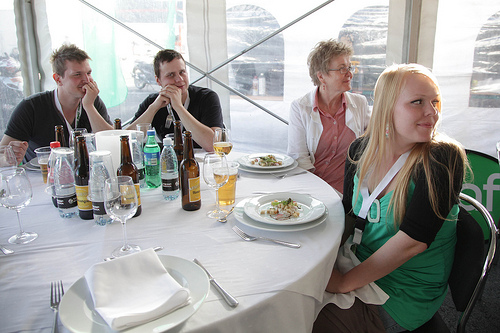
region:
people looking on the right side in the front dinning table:
[202, 10, 490, 307]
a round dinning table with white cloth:
[7, 137, 340, 331]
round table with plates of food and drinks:
[4, 122, 330, 308]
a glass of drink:
[209, 122, 236, 157]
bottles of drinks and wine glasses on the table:
[31, 117, 243, 239]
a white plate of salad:
[231, 177, 328, 249]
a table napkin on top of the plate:
[35, 235, 222, 331]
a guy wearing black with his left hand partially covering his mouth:
[2, 37, 128, 201]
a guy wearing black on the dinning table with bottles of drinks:
[123, 33, 231, 231]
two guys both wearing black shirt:
[5, 35, 238, 215]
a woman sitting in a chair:
[351, 61, 457, 322]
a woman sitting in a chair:
[285, 36, 373, 176]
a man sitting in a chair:
[128, 46, 232, 153]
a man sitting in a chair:
[7, 45, 112, 155]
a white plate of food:
[221, 182, 331, 230]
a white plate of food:
[231, 142, 301, 174]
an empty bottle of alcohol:
[171, 128, 204, 213]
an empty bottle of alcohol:
[117, 134, 142, 219]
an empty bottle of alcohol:
[70, 132, 91, 215]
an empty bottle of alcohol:
[171, 117, 183, 164]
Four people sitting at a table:
[7, 6, 479, 331]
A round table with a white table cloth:
[6, 135, 342, 330]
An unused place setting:
[37, 230, 245, 331]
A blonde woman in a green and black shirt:
[340, 62, 477, 292]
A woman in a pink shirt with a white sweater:
[285, 36, 377, 201]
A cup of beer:
[205, 157, 242, 216]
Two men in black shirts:
[14, 35, 232, 167]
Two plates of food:
[230, 149, 330, 256]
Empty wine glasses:
[1, 147, 231, 259]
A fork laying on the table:
[225, 217, 307, 259]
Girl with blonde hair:
[365, 60, 451, 162]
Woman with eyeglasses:
[305, 30, 356, 106]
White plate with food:
[235, 185, 328, 226]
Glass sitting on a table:
[100, 172, 141, 254]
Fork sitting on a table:
[38, 273, 68, 329]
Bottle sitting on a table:
[170, 125, 203, 215]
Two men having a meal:
[0, 37, 227, 167]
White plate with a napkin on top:
[56, 245, 212, 330]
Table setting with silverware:
[45, 238, 245, 329]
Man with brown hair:
[147, 46, 197, 101]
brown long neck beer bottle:
[179, 131, 204, 217]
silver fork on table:
[37, 276, 72, 332]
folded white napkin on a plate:
[80, 251, 206, 326]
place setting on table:
[27, 232, 240, 329]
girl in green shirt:
[338, 51, 482, 326]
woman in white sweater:
[298, 35, 363, 173]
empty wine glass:
[96, 171, 143, 248]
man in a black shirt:
[114, 45, 230, 155]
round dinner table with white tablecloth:
[6, 111, 351, 332]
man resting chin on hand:
[15, 23, 107, 203]